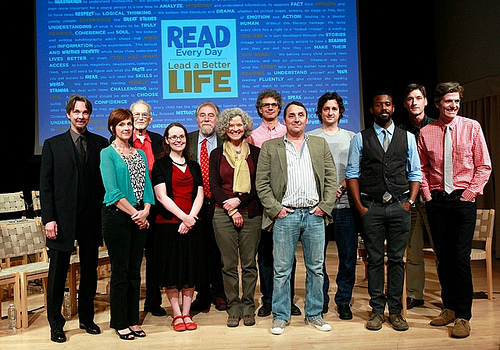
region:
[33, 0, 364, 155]
Read Every Day sign on big screen tv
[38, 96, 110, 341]
a man wearing a black suit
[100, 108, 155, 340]
woman wearing a blue sweater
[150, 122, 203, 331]
woman wearing a red shirt and black skirt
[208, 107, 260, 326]
a woman with grey hair and neck scarf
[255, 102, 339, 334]
a man wearing a grey jacket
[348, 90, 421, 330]
a man wearing a black vest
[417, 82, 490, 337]
a man wearing a pink shirt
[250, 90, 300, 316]
a man wearing glasses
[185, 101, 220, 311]
a man wearing a red tie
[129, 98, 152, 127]
a man wearing glasses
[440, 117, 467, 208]
a man wearing a tie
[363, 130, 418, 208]
a man wearing a black vest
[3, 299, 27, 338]
A water bottle on the floor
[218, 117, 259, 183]
a woman wearing a scarf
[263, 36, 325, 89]
words on a blue screen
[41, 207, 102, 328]
a man wearing black pants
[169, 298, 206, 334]
a woman wearing red shoes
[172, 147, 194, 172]
a woman wearing a necklace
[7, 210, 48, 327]
a chair in the room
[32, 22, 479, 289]
people standing inside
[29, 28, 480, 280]
people standing in a group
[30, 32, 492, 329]
group of people standing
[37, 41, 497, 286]
a group of people smiling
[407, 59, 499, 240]
a man wearing a red shirt and tie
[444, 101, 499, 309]
a man wearing a red shirt and black pants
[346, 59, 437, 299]
a man wearing a black vest over blue shirt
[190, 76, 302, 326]
a woman wearing a scarf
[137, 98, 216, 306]
a woman wearing a red shirt and black skirt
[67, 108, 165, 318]
a woman wearing a blue shirt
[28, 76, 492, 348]
group of adults posing for a picture on stage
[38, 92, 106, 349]
a man in a black suit standing on stage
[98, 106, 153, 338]
a woman in a turquoise sweater standing on stage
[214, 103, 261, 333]
a woman with a gold scarf standing on stage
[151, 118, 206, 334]
a woman with bright red shoes standing on stage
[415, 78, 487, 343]
a man in a pink dress shirt standing on stage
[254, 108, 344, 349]
a man in stonewash jeans standing on stage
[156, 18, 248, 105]
Read Every Day Lead a Better Life sign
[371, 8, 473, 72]
black background on the stage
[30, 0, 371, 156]
advertisement to encourage the art of reading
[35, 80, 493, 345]
group of people encouraging the art of reading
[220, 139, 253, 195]
woman's tan neck scarf around neck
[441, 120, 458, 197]
light-colored man's tie around man's neck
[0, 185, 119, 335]
rows of chairs for sitting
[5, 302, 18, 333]
bottle of water beneath chair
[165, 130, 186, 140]
pair of glasses on woman's face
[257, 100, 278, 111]
pair of glasses on man's face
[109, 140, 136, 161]
beaded necklace around woman's neck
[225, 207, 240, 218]
yellow bangle bracelet on woman's wrist